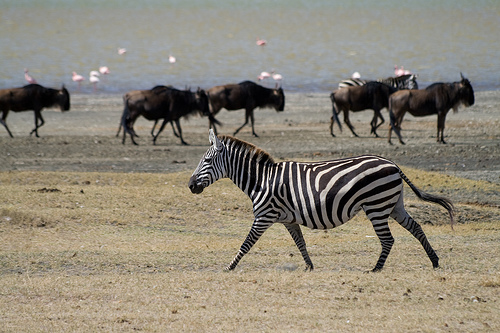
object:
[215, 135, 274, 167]
hair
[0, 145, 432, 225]
ground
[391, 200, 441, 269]
leg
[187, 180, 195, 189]
nose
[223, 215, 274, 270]
front leg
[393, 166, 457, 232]
tail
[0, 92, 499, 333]
ground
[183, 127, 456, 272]
zebra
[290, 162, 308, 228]
zebra stripes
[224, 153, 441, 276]
body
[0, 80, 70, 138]
animal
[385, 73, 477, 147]
animal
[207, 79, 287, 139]
animal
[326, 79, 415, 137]
animal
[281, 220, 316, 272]
leg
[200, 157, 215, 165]
eye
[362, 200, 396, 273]
hind leg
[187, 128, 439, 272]
coat